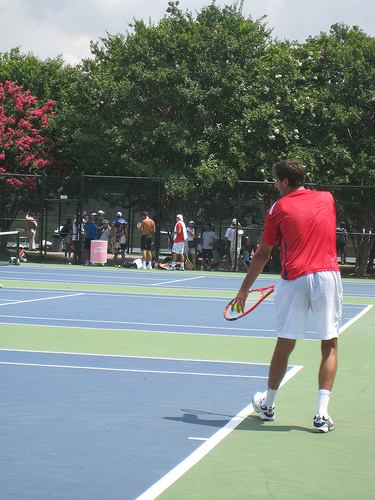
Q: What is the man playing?
A: Tennis.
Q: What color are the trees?
A: Green.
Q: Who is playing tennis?
A: A man.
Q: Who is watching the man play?
A: Spectators.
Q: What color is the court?
A: Blue and green.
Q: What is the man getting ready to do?
A: Serve.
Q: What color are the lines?
A: White.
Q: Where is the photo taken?
A: On a tennis court.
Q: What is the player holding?
A: A racket.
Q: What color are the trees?
A: Green.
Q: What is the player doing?
A: Preparing to hit the ball.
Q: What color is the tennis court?
A: Blue, green and white.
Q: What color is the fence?
A: Black.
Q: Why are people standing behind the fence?
A: They are watching the tennis game.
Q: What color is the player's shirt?
A: Red.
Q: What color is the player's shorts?
A: White.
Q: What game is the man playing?
A: Tennis.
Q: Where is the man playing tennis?
A: Tennis court.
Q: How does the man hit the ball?
A: Tennis racket.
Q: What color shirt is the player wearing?
A: Red.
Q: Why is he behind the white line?
A: Serving the ball.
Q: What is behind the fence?
A: Trees.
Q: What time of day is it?
A: Daytime.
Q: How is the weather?
A: Sunny.